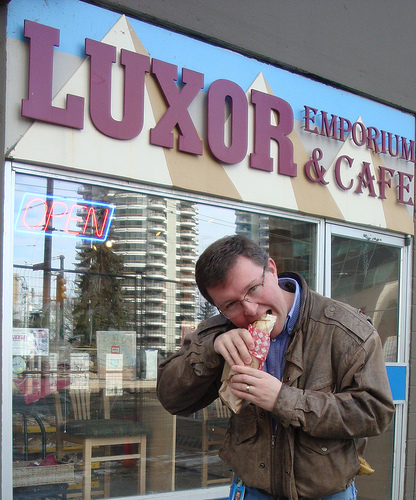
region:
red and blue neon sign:
[16, 187, 118, 245]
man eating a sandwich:
[145, 230, 396, 496]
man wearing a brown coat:
[152, 229, 401, 499]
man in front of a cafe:
[151, 230, 397, 498]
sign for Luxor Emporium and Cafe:
[7, 73, 414, 238]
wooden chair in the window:
[39, 341, 153, 498]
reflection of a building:
[71, 179, 203, 362]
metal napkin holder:
[137, 346, 160, 382]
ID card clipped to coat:
[225, 477, 246, 498]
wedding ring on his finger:
[241, 382, 255, 393]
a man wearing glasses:
[206, 278, 279, 311]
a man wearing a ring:
[240, 366, 257, 405]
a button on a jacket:
[323, 296, 340, 321]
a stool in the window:
[61, 399, 177, 493]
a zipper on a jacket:
[268, 422, 290, 493]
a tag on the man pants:
[235, 466, 251, 498]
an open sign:
[19, 188, 114, 239]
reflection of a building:
[128, 183, 183, 281]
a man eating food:
[241, 291, 290, 355]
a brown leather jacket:
[304, 290, 380, 445]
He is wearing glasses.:
[217, 273, 286, 323]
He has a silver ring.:
[237, 382, 251, 394]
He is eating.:
[185, 234, 294, 372]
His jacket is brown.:
[158, 301, 397, 489]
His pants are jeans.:
[224, 481, 348, 498]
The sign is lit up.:
[19, 183, 119, 243]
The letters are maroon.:
[17, 22, 413, 208]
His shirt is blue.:
[259, 337, 297, 388]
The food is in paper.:
[217, 314, 284, 406]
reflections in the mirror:
[24, 177, 258, 483]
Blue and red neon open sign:
[14, 192, 115, 243]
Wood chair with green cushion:
[49, 368, 147, 498]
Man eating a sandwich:
[154, 234, 394, 499]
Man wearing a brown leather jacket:
[154, 232, 395, 499]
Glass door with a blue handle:
[319, 218, 409, 499]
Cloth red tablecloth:
[11, 377, 71, 403]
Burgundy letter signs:
[18, 15, 414, 208]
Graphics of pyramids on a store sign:
[3, 13, 414, 235]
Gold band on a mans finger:
[240, 381, 251, 393]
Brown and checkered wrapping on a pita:
[218, 309, 275, 414]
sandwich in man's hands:
[208, 313, 285, 420]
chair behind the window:
[55, 415, 165, 497]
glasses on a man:
[206, 282, 271, 316]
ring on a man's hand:
[244, 379, 253, 397]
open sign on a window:
[14, 181, 122, 257]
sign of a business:
[22, 10, 413, 257]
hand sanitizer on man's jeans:
[222, 475, 249, 498]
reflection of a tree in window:
[72, 243, 136, 364]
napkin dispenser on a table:
[131, 343, 164, 389]